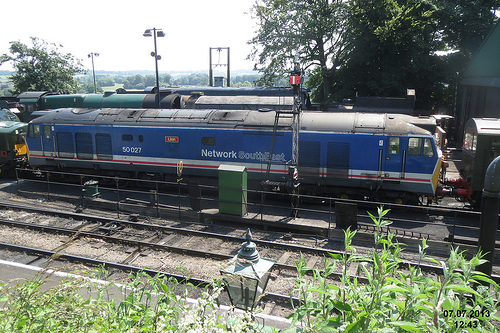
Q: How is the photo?
A: Clear.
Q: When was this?
A: Daytime.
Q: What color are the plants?
A: Green.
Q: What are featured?
A: Trains.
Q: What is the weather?
A: Sunny.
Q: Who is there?
A: No one.